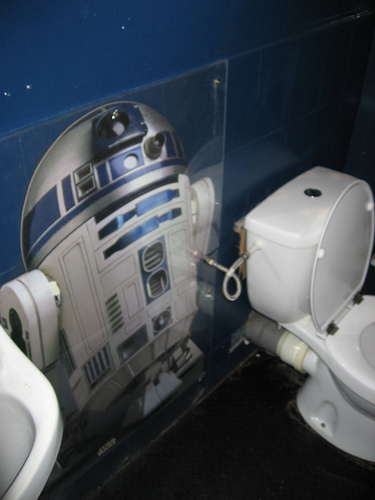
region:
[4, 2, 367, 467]
blue bathroom wall with poster covered in plastic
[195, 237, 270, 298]
looped pipe between wall and toilet tank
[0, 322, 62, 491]
curved edge of white sink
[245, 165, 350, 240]
silver button on top of toilet lid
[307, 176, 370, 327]
toilet lid leaning against toilet tank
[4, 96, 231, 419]
round mechanical character from futuristic movie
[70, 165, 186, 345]
body of blue and white panels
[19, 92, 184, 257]
semicircular dome for head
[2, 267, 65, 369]
flat and curved appendages for arms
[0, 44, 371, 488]
this is a bathroom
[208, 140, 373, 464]
this is a white toilet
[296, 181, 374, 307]
toilet lid is up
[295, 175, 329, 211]
silver flush button on toilet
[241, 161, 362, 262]
a white commode cover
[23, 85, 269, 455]
a picture of r2d2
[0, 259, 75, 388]
toilet paper on wall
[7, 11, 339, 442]
blue wall in bathroom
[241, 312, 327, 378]
grey and white pipe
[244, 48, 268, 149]
Small blue grout line on wall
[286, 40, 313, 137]
Small blue grout line on wall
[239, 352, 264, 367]
Small patched of dirt onthe ground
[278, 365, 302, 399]
Small patched of dirt onthe ground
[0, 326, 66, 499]
a sink on right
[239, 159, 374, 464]
toilet stool in white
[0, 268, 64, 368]
tissue roll on roller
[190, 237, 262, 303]
hose from wall to toilet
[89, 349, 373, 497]
the restroom floor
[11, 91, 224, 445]
picture on wall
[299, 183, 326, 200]
flusher on top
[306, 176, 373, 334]
the lid up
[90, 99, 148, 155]
a hand dryer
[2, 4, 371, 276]
the blue walls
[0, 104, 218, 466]
A picture on the wall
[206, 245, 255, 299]
A small tube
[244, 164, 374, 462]
A large white toilet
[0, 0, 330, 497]
a large blue wall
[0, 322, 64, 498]
a small white sink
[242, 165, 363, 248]
A toilet basin cover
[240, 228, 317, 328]
A white toilet basin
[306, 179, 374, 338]
A white toilet lid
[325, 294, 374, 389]
A white toilet seat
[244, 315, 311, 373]
A large pipe in the wall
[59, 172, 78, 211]
blue metallic part of android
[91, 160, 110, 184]
blue metallic part of android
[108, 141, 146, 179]
blue metallic part of android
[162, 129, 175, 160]
blue metallic part of android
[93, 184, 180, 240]
blue metallic part of android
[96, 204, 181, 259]
blue metallic part of android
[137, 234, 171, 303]
blue metallic part of android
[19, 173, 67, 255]
blue metallic part of android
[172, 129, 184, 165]
blue metallic part of android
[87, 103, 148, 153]
blue metallic part of android